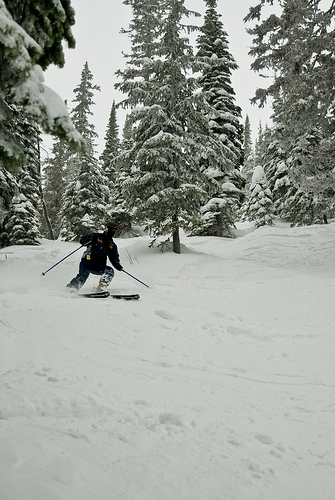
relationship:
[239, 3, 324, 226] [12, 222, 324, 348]
trees covered in snow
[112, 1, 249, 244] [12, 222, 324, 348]
trees covered in snow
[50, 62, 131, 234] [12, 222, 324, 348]
trees covered in snow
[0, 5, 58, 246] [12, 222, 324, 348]
trees covered in snow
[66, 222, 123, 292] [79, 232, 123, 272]
man with black ski jacket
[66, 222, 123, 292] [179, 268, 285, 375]
man in snow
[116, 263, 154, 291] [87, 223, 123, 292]
pole on man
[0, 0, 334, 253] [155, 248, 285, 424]
trees on ground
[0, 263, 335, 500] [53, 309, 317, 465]
snow on ground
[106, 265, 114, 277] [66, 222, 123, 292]
left knee of man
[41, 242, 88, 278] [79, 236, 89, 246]
pole in hand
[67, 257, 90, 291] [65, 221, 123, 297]
right leg of person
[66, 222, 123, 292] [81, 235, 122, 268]
man wearing jacket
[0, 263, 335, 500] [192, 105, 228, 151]
snow covered branch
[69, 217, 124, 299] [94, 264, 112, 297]
man covered leg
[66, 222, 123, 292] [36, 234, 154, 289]
man using ski poles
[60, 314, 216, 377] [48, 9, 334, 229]
snow under trees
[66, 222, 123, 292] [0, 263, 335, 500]
man rushing down snow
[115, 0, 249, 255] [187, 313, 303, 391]
tree in snow